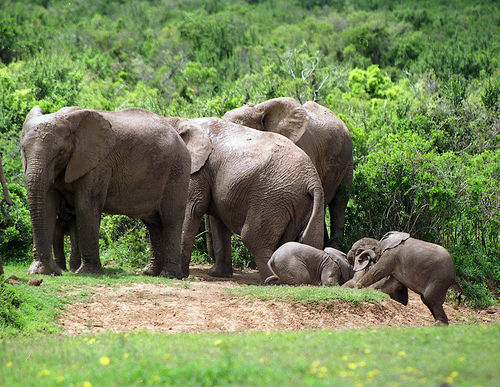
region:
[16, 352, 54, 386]
Small patch of grass in the field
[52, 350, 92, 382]
Small patch of grass in the field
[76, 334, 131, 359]
Small patch of grass in the field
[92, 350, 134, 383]
Small patch of grass in the field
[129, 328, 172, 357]
Small patch of grass in the field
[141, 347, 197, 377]
Small patch of grass in the field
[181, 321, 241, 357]
Small patch of grass in the field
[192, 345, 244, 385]
Small patch of grass in the field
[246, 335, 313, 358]
Small patch of grass in the field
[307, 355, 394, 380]
Small patch of grass in the field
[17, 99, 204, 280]
grey adult elephant standing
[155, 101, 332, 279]
grey adult elephant standing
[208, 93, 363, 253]
adult grey elephant standing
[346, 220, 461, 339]
baby elephant standing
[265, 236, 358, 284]
baby elephant crouching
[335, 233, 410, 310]
baby elephant sitting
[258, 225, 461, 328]
three baby elephants playing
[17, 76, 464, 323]
grey elephant family in forest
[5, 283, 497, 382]
gren grass with yellow flowers and dirt patch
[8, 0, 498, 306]
gren trees in forest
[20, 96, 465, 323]
the elephants in a herd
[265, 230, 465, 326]
the two small elephants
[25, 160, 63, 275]
the trunk on the elephant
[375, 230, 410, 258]
the ear on the small elephant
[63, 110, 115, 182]
the ear on the large elephant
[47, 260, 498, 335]
the dirt on the ground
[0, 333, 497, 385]
the yellow flowers on the grass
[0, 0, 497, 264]
the bushes near the elephants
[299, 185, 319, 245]
the tail on the elephant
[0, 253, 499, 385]
the grass near the elepants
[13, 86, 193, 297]
This is an elephant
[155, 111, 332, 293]
This is an elephant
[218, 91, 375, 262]
This is an elephant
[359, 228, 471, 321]
This is an elephant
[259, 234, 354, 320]
This is an elephant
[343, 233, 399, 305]
This is an elephant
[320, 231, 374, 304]
This is an elephant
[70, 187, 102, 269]
Leg of an elephant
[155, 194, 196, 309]
Leg of an elephant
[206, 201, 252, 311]
Leg of an elephant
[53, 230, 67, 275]
leg of an elephant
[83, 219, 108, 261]
leg of an elephant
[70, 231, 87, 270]
leg of an elephant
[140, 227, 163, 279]
leg of an elephant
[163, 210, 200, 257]
leg of an elephant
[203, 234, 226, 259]
leg of an elephant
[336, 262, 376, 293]
leg of an elephant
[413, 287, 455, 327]
leg of an elephant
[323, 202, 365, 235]
leg of an elephant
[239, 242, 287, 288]
leg of an elephant